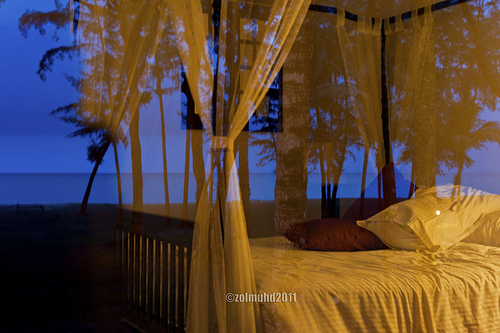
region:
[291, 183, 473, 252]
the pillows are on the bed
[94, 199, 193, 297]
the bed rail is wooden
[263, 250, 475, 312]
the sheets are wrinkled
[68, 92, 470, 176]
the palm trees are on the beach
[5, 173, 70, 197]
the water is calm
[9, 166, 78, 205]
the water is still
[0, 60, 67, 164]
the sky is getting dark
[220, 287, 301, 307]
the watermark is white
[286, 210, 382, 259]
the pillow is red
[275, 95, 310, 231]
the tree trunk is brown and thick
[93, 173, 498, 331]
A bed against the wall.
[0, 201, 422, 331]
The wall is short.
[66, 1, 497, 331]
Netting around the bed.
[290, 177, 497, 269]
Pillows on the bed.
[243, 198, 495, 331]
The bed is made.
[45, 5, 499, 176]
Trees outside the building.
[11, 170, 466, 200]
Ocean in the distance.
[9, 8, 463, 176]
The sky is blue.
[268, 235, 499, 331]
Stripes on the comforter.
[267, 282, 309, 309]
The photo was taken in 2011.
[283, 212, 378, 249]
A small red pillow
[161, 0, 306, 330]
a large white canopy cover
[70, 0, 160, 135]
a large white canopy cover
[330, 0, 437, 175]
a large white canopy cover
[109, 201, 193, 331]
a large wooden foot board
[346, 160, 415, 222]
a small red pillow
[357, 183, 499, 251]
a large white pillow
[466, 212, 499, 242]
a large white pillow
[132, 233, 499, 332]
A large bed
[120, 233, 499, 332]
a set of white sheets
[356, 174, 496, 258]
the pillow is white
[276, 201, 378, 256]
the pillow is red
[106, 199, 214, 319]
the headboard of bed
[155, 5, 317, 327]
a curtain on side the bed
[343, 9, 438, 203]
a curtain on the corner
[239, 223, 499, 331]
a white comforter on bed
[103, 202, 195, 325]
headboard is brown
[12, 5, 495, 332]
trees behind a bed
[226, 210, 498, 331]
the bed is wrinkled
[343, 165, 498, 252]
the cover of pillow is white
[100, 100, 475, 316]
a bed that is outside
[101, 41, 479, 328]
a bed with curtains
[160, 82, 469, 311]
a bed with pillows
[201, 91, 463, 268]
a bed with white pillow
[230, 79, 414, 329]
a bed with red pillow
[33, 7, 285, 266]
trees with leaves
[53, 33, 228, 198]
leaves on a tree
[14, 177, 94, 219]
a body of water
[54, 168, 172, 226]
a body of calm water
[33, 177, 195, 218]
a calm body of water